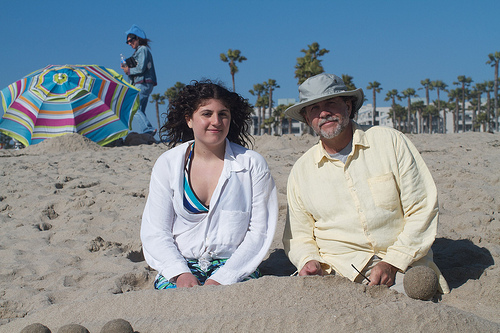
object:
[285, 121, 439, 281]
shirt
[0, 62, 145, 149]
rainbow umbrella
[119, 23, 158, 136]
lady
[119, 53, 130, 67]
bottle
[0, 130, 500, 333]
sand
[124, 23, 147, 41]
hat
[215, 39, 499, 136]
palm trees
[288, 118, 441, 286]
body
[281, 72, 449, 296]
man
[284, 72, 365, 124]
grey hat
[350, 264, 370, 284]
glasses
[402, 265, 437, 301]
ball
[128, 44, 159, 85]
shirt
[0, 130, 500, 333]
beach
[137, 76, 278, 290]
lady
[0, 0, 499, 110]
sky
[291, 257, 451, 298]
brown pants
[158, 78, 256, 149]
hair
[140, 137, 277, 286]
shirt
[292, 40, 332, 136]
tree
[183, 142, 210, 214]
top